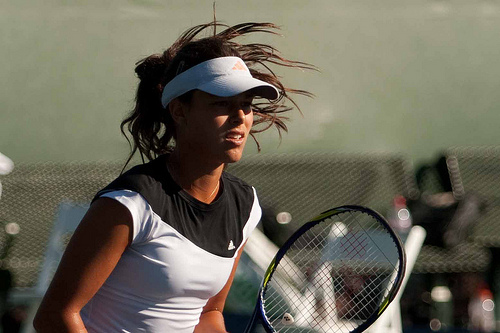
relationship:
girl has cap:
[32, 21, 319, 332] [160, 55, 277, 102]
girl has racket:
[32, 39, 262, 331] [246, 200, 405, 331]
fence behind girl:
[3, 167, 496, 270] [102, 36, 350, 327]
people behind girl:
[287, 144, 497, 290] [32, 0, 291, 331]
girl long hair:
[32, 21, 319, 332] [124, 26, 286, 161]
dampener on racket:
[277, 281, 327, 321] [246, 200, 405, 331]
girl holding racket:
[32, 21, 319, 332] [246, 200, 405, 331]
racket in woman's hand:
[245, 205, 410, 333] [198, 308, 251, 329]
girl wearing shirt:
[32, 21, 319, 332] [79, 154, 263, 331]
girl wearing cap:
[32, 21, 319, 332] [155, 55, 278, 107]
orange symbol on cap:
[232, 60, 247, 69] [155, 55, 278, 107]